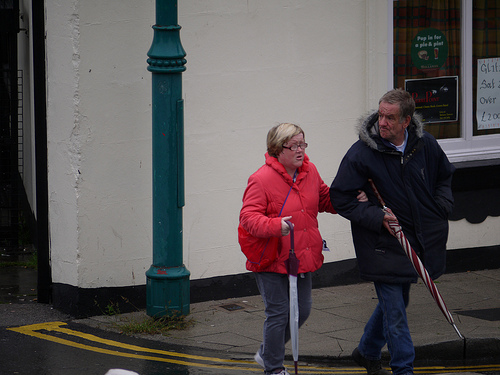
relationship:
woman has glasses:
[247, 119, 334, 372] [283, 141, 311, 154]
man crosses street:
[335, 78, 460, 374] [60, 325, 381, 373]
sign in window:
[474, 54, 498, 137] [396, 7, 493, 136]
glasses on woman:
[283, 141, 311, 154] [247, 119, 334, 372]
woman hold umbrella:
[247, 119, 334, 372] [283, 219, 302, 371]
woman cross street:
[247, 119, 334, 372] [60, 325, 381, 373]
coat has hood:
[324, 127, 461, 284] [353, 105, 377, 154]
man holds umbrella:
[335, 78, 460, 374] [364, 174, 479, 353]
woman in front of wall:
[247, 119, 334, 372] [67, 28, 131, 253]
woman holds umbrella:
[247, 119, 334, 372] [283, 219, 306, 371]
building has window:
[38, 1, 226, 289] [396, 7, 493, 136]